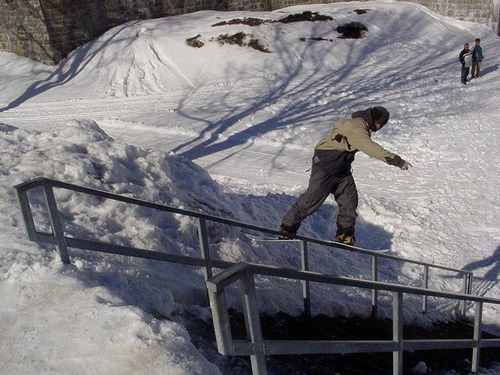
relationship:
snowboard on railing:
[243, 229, 388, 257] [13, 177, 499, 375]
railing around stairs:
[13, 177, 499, 375] [157, 310, 498, 374]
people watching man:
[460, 39, 485, 85] [279, 106, 414, 246]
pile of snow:
[0, 117, 342, 270] [2, 1, 496, 374]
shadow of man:
[456, 241, 499, 282] [279, 106, 414, 246]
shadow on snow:
[456, 241, 499, 282] [2, 1, 496, 374]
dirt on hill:
[187, 8, 370, 52] [52, 0, 487, 87]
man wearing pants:
[279, 106, 414, 246] [281, 167, 357, 233]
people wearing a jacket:
[458, 42, 472, 84] [460, 48, 474, 71]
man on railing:
[279, 106, 414, 246] [13, 177, 499, 375]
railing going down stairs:
[13, 177, 499, 375] [157, 310, 498, 374]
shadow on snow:
[169, 8, 499, 167] [2, 1, 496, 374]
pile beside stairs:
[0, 117, 342, 270] [157, 310, 498, 374]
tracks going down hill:
[110, 18, 195, 97] [52, 0, 487, 87]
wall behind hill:
[1, 0, 499, 65] [52, 0, 487, 87]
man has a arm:
[279, 106, 414, 246] [353, 131, 413, 172]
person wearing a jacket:
[473, 37, 484, 79] [472, 45, 483, 62]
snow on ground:
[2, 1, 496, 374] [1, 1, 499, 374]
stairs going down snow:
[157, 310, 498, 374] [2, 1, 496, 374]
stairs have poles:
[157, 310, 498, 374] [41, 183, 483, 374]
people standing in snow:
[460, 39, 485, 85] [2, 1, 496, 374]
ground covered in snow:
[1, 1, 499, 374] [2, 1, 496, 374]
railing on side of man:
[13, 177, 499, 375] [279, 106, 414, 246]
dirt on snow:
[187, 8, 370, 52] [2, 1, 496, 374]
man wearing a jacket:
[279, 106, 414, 246] [314, 119, 405, 179]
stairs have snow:
[157, 310, 498, 374] [2, 1, 496, 374]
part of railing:
[205, 261, 499, 374] [13, 177, 499, 375]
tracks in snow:
[110, 18, 195, 97] [2, 1, 496, 374]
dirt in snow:
[187, 8, 370, 52] [2, 1, 496, 374]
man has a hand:
[279, 106, 414, 246] [400, 159, 411, 171]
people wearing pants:
[458, 42, 472, 84] [460, 66, 470, 83]